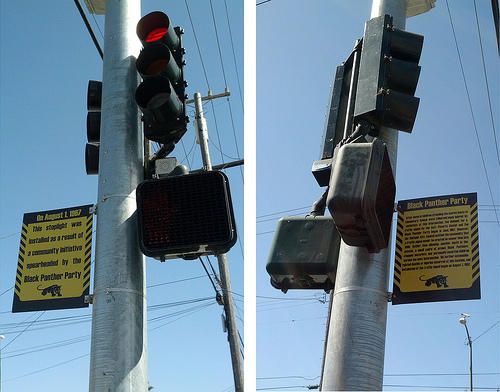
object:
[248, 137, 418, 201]
person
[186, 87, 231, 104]
transformer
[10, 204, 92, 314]
sign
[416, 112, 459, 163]
wall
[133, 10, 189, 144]
traffic light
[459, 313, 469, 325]
light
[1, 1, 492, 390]
blue sky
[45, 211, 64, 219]
word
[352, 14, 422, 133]
traffic light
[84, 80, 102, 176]
traffic light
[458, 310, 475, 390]
street lamp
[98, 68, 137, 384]
shadow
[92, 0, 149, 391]
pole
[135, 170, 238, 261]
signal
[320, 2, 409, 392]
pole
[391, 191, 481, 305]
sign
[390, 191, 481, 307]
background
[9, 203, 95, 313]
background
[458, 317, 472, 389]
lamppost